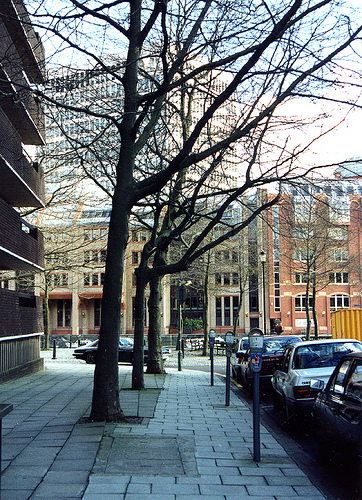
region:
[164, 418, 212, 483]
the sidewalk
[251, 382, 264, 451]
a pole on the meter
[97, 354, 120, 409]
the tree trunk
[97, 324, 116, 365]
bark on the tree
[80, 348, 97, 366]
back tire on the car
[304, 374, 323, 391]
side mirror on the car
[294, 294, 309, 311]
windows on the building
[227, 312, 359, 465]
the cars are parked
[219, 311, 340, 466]
the cars are parked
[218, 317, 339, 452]
the cars are parked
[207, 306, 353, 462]
the cars are parked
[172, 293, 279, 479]
parking meters at the sidewalk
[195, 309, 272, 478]
parking meters at the sidewalk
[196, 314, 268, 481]
parking meters at the sidewalk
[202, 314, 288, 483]
parking meters at the sidewalk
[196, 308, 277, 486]
parking meters at the sidewalk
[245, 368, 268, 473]
Pole on a parking meter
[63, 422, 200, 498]
Stone on a sidewalk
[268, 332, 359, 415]
White car parked by a sidewalk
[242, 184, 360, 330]
Brown brick building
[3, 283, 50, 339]
Porch on a building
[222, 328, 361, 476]
Cars parked by a sidewalk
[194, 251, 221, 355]
Tall, and skinny tree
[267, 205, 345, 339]
Windows on a building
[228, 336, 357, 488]
four cars parked next to the curb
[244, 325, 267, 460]
a metal parking meter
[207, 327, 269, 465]
three metal parking meters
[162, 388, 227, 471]
a white brick sidewalk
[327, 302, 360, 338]
a yellow metal container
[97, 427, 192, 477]
access panels on a sidewalk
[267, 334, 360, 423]
a white car parked next to a curb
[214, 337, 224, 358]
a pic nic table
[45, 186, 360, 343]
a series of apartment buildings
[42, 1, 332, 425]
a line of trees on a brick sidewalk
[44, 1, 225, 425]
a tree with no leaves on it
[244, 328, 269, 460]
a parking meter by a street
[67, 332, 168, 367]
a black car obscured by trees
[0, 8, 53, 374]
a five story parkign space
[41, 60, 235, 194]
a tall building overlooking the city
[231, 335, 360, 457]
a row of old cars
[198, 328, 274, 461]
a line of parking meters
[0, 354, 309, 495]
a brick sidewalk io a street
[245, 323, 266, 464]
parking meter on sidewalk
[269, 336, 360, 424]
white car parked at curb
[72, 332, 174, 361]
black car at corner